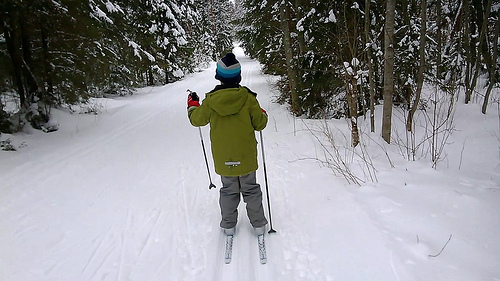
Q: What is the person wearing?
A: Coat.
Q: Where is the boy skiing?
A: Snow.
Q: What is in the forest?
A: Trees.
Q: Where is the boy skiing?
A: Trail.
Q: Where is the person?
A: Snow.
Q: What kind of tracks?
A: Ski tracks.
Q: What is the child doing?
A: Small child cross country skiing.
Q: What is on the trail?
A: Fresh snow on a trail.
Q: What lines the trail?
A: Pine trees lining a trail.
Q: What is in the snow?
A: Small twigs in the snow.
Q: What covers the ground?
A: The ground is covered in snow.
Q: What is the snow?
A: The snow is white.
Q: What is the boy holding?
A: The boy is holding ski poles.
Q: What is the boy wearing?
A: The boy is wearing skis.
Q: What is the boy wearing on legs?
A: The boy is wearing pants.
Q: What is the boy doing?
A: Skiing.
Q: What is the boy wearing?
A: A coat.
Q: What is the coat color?
A: Green.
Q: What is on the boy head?
A: A cap.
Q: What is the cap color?
A: Blue and white.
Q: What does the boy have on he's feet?
A: Skis.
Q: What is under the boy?
A: Snow.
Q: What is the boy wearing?
A: Pants.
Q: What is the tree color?
A: Brown.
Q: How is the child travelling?
A: By skis.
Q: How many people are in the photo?
A: One.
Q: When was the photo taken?
A: Daytime.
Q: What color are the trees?
A: Green.